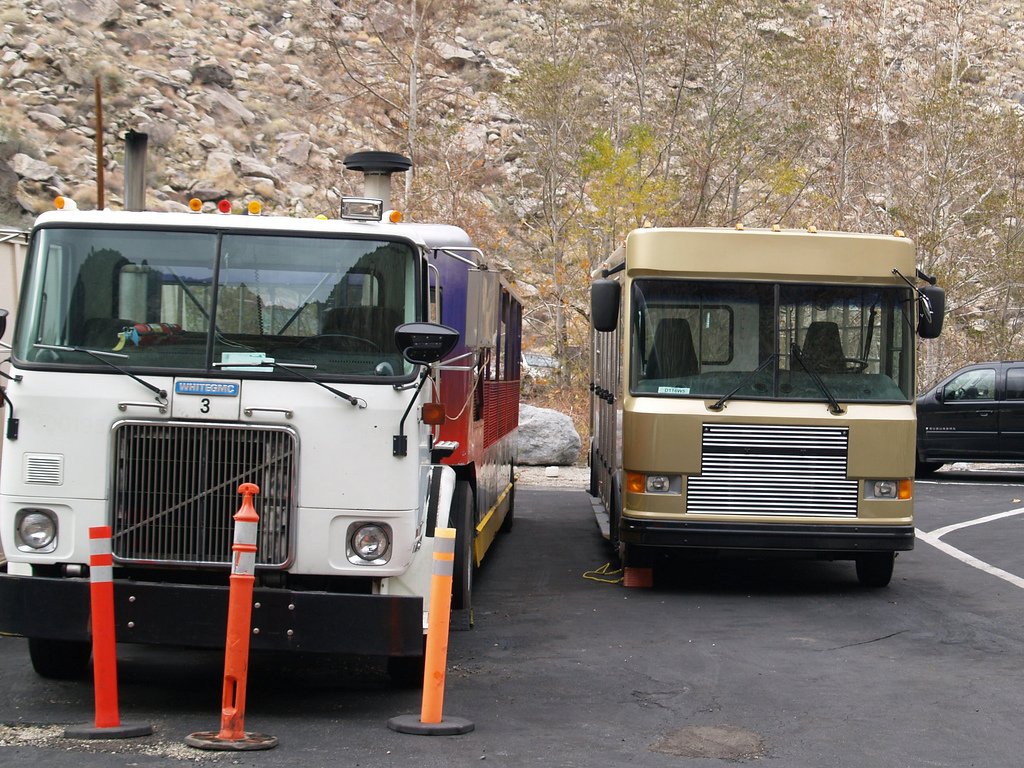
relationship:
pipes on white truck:
[96, 116, 442, 225] [0, 126, 523, 691]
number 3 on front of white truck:
[184, 385, 220, 420] [0, 126, 523, 691]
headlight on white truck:
[1, 500, 72, 583] [0, 126, 523, 691]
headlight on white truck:
[325, 512, 414, 583] [0, 126, 523, 691]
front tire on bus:
[584, 518, 676, 601] [566, 216, 958, 600]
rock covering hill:
[165, 120, 230, 178] [7, 4, 1019, 227]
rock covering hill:
[272, 120, 320, 178] [7, 4, 1019, 227]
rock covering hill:
[253, 28, 301, 61] [7, 4, 1019, 227]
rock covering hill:
[330, 12, 378, 38] [7, 4, 1019, 227]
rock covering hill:
[431, 39, 480, 72] [7, 4, 1019, 227]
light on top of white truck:
[42, 181, 84, 213] [0, 126, 523, 691]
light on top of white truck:
[178, 184, 226, 213] [0, 126, 523, 691]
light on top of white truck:
[215, 186, 247, 213] [0, 126, 523, 691]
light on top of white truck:
[238, 192, 277, 213] [0, 126, 523, 691]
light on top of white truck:
[373, 190, 418, 222] [0, 126, 523, 691]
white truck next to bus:
[1, 202, 565, 694] [566, 216, 958, 600]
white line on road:
[915, 503, 1024, 586] [891, 597, 1022, 659]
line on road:
[914, 532, 1022, 610] [891, 597, 1022, 659]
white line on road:
[921, 503, 1020, 549] [847, 597, 950, 665]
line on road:
[914, 506, 1023, 590] [847, 597, 950, 665]